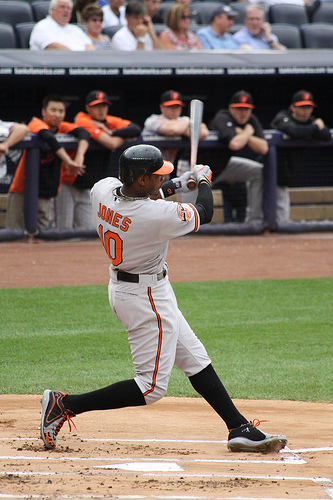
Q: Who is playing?
A: Orioles.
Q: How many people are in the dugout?
A: 5.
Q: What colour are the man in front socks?
A: Black.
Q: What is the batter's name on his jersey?
A: Jones.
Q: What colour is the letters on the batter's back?
A: Orange.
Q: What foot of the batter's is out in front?
A: Left.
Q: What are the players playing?
A: Baseball.